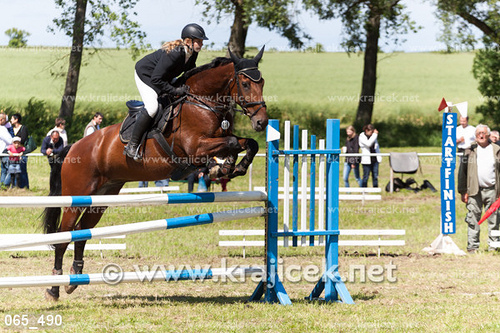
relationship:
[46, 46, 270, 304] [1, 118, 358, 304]
horse jumping over hurdle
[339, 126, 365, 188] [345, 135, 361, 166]
woman has coat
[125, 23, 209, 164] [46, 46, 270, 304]
woman riding horse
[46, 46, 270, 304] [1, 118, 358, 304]
horse going over hurdle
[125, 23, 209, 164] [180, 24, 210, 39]
woman has helmet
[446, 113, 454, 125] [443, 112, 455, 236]
letter on sign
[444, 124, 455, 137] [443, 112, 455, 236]
letter on sign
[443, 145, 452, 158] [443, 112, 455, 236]
letter on sign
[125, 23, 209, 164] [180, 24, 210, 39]
woman wearing helmet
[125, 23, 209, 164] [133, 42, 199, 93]
woman wearing jacket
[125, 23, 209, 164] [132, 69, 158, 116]
woman wearing riding pants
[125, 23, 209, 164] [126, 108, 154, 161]
woman wearing boots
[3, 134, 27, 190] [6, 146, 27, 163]
kid wearing shirt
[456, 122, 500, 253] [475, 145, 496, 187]
man wearing shirt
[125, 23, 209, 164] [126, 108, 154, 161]
woman has boots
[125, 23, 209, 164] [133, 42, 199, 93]
woman has jacket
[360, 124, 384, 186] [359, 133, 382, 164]
woman has coat